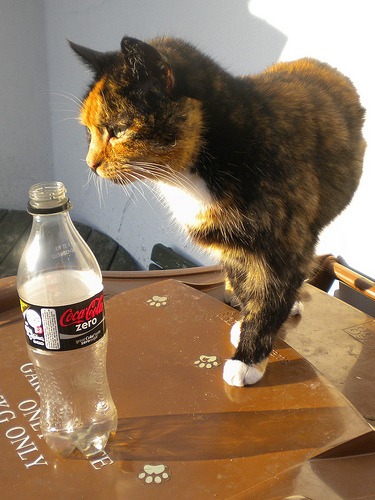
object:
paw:
[227, 315, 248, 349]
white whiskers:
[80, 158, 87, 162]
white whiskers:
[99, 177, 106, 209]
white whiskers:
[120, 179, 137, 206]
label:
[38, 308, 60, 351]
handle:
[325, 253, 374, 308]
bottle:
[17, 175, 122, 463]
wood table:
[0, 206, 140, 276]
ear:
[66, 39, 114, 74]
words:
[3, 424, 49, 474]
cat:
[67, 32, 369, 391]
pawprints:
[194, 353, 219, 372]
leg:
[222, 250, 290, 362]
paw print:
[145, 292, 169, 310]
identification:
[58, 294, 105, 328]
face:
[77, 52, 202, 186]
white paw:
[291, 298, 305, 317]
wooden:
[145, 241, 197, 275]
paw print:
[136, 462, 171, 485]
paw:
[221, 356, 269, 389]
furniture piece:
[0, 249, 375, 499]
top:
[24, 177, 73, 219]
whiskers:
[117, 169, 164, 224]